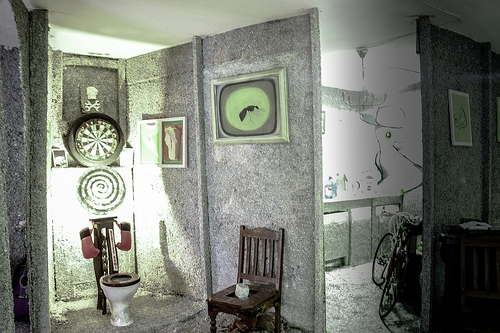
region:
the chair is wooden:
[254, 289, 256, 305]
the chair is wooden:
[256, 295, 264, 311]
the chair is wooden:
[257, 286, 277, 313]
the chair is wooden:
[256, 297, 270, 302]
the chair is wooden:
[257, 292, 267, 308]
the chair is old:
[209, 222, 279, 313]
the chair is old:
[243, 245, 280, 319]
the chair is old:
[222, 251, 302, 319]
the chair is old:
[243, 240, 270, 275]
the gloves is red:
[69, 220, 111, 265]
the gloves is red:
[62, 212, 167, 303]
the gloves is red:
[83, 212, 233, 326]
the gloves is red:
[85, 192, 160, 273]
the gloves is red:
[52, 172, 199, 310]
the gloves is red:
[105, 220, 189, 278]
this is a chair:
[217, 225, 277, 320]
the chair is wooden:
[245, 230, 275, 260]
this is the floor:
[135, 290, 165, 325]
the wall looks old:
[210, 155, 315, 200]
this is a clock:
[75, 120, 115, 145]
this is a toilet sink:
[95, 270, 135, 315]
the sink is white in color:
[110, 290, 120, 300]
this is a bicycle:
[370, 230, 405, 305]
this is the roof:
[70, 35, 125, 45]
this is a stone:
[231, 280, 246, 292]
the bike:
[377, 258, 396, 305]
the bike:
[396, 224, 413, 266]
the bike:
[375, 264, 409, 317]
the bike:
[384, 263, 399, 285]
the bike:
[387, 257, 402, 304]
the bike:
[396, 270, 406, 292]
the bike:
[373, 220, 393, 267]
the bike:
[402, 203, 419, 258]